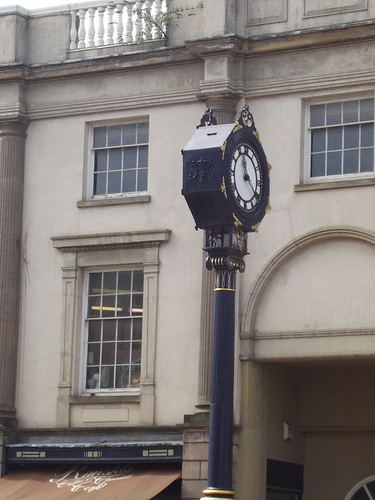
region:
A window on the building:
[80, 114, 151, 202]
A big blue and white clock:
[175, 92, 275, 498]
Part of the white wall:
[36, 165, 69, 200]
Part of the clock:
[239, 180, 244, 193]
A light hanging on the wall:
[88, 302, 124, 313]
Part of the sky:
[29, 3, 38, 6]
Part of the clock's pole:
[214, 396, 227, 427]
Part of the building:
[261, 63, 303, 79]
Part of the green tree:
[140, 10, 157, 29]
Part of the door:
[274, 469, 293, 479]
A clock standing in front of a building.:
[87, 99, 317, 498]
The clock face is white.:
[223, 137, 264, 210]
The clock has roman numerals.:
[227, 137, 266, 210]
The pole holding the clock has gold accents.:
[180, 97, 273, 295]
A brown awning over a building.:
[6, 465, 177, 496]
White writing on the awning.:
[39, 463, 133, 494]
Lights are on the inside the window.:
[89, 279, 142, 370]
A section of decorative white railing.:
[64, 1, 172, 48]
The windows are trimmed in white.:
[79, 110, 371, 397]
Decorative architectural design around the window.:
[50, 227, 170, 428]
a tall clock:
[171, 81, 291, 498]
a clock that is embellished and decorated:
[170, 78, 298, 308]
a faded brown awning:
[8, 459, 185, 498]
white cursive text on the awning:
[49, 463, 132, 499]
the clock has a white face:
[218, 109, 272, 222]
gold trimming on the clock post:
[195, 480, 236, 495]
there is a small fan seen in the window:
[81, 356, 115, 394]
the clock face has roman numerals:
[220, 128, 280, 226]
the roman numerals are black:
[232, 137, 267, 218]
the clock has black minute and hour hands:
[239, 143, 264, 214]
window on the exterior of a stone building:
[303, 96, 374, 182]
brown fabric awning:
[0, 459, 183, 498]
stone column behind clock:
[195, 231, 217, 409]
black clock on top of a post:
[180, 103, 271, 227]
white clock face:
[229, 141, 263, 211]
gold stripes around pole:
[199, 488, 237, 499]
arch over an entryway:
[241, 226, 374, 358]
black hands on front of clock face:
[241, 151, 261, 200]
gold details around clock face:
[220, 176, 229, 196]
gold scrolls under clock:
[205, 257, 246, 272]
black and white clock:
[180, 125, 282, 244]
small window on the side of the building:
[73, 120, 159, 213]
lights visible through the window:
[89, 301, 141, 318]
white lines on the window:
[78, 272, 144, 390]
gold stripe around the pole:
[210, 285, 239, 295]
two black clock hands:
[242, 151, 262, 202]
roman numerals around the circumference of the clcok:
[224, 142, 265, 212]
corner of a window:
[343, 472, 371, 499]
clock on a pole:
[169, 105, 279, 499]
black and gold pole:
[193, 248, 243, 498]